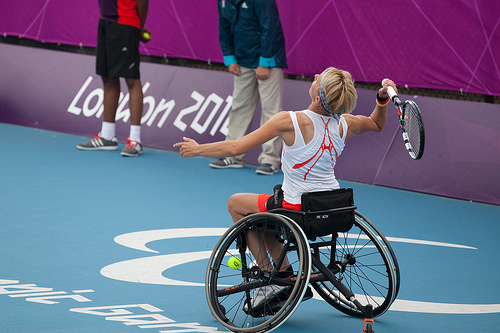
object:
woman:
[172, 66, 398, 312]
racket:
[381, 78, 425, 160]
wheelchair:
[205, 184, 401, 333]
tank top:
[281, 109, 349, 204]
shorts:
[258, 194, 301, 213]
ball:
[228, 256, 242, 270]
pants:
[225, 67, 284, 169]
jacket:
[216, 0, 288, 68]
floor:
[0, 124, 500, 333]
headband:
[319, 69, 341, 125]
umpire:
[215, 0, 288, 175]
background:
[0, 0, 500, 204]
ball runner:
[75, 0, 151, 157]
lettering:
[0, 226, 497, 333]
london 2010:
[67, 76, 233, 137]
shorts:
[96, 19, 142, 79]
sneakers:
[120, 136, 143, 157]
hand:
[378, 80, 398, 99]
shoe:
[76, 131, 117, 151]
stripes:
[91, 138, 104, 147]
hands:
[227, 64, 270, 80]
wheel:
[204, 212, 312, 333]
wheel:
[363, 318, 373, 333]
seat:
[250, 188, 357, 242]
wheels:
[308, 209, 401, 318]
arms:
[173, 110, 288, 158]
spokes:
[216, 219, 299, 328]